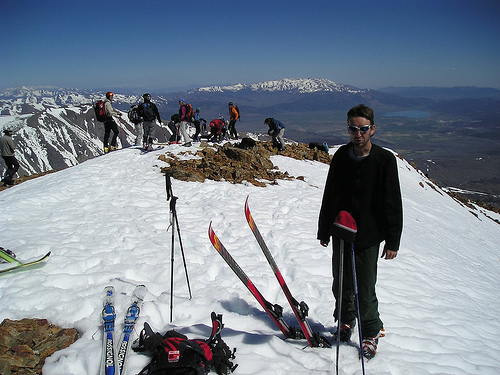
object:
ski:
[0, 250, 19, 264]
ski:
[2, 251, 54, 277]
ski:
[94, 281, 118, 372]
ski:
[116, 282, 147, 374]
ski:
[205, 217, 305, 343]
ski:
[241, 194, 332, 349]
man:
[314, 106, 405, 360]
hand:
[380, 248, 398, 261]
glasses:
[347, 125, 372, 132]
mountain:
[189, 75, 374, 100]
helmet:
[106, 91, 114, 96]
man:
[95, 91, 122, 154]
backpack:
[93, 99, 107, 122]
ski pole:
[167, 199, 177, 321]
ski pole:
[163, 171, 193, 299]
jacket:
[229, 106, 239, 120]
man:
[227, 102, 240, 141]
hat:
[178, 98, 185, 104]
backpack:
[187, 102, 195, 122]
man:
[177, 98, 196, 148]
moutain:
[2, 136, 499, 371]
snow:
[0, 156, 492, 375]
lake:
[383, 108, 431, 118]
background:
[15, 87, 497, 125]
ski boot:
[329, 311, 355, 345]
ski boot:
[357, 329, 382, 361]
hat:
[332, 210, 358, 243]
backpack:
[131, 312, 239, 374]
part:
[349, 166, 376, 200]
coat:
[316, 143, 403, 249]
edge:
[10, 312, 77, 332]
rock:
[0, 319, 74, 374]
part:
[161, 138, 263, 179]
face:
[349, 117, 371, 147]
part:
[440, 152, 462, 162]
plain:
[399, 107, 498, 173]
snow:
[237, 80, 337, 87]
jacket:
[104, 100, 117, 118]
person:
[2, 130, 20, 186]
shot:
[1, 2, 495, 370]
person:
[138, 93, 162, 153]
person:
[210, 118, 226, 145]